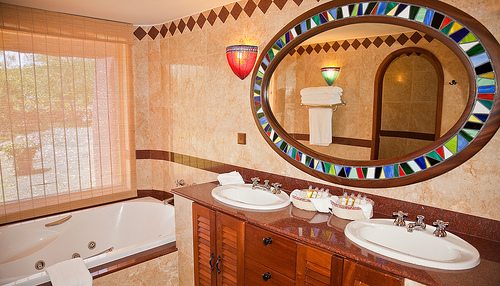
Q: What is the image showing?
A: It is showing a bathroom.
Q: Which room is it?
A: It is a bathroom.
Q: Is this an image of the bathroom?
A: Yes, it is showing the bathroom.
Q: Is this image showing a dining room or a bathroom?
A: It is showing a bathroom.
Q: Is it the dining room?
A: No, it is the bathroom.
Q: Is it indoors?
A: Yes, it is indoors.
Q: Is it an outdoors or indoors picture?
A: It is indoors.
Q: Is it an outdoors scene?
A: No, it is indoors.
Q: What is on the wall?
A: The sconce is on the wall.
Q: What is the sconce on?
A: The sconce is on the wall.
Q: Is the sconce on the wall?
A: Yes, the sconce is on the wall.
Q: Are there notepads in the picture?
A: No, there are no notepads.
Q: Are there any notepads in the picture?
A: No, there are no notepads.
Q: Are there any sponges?
A: No, there are no sponges.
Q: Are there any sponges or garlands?
A: No, there are no sponges or garlands.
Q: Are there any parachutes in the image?
A: No, there are no parachutes.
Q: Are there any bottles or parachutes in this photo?
A: No, there are no parachutes or bottles.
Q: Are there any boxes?
A: No, there are no boxes.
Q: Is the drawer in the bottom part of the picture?
A: Yes, the drawer is in the bottom of the image.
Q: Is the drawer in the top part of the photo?
A: No, the drawer is in the bottom of the image.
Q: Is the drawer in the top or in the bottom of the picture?
A: The drawer is in the bottom of the image.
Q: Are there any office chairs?
A: No, there are no office chairs.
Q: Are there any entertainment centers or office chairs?
A: No, there are no office chairs or entertainment centers.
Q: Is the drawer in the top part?
A: No, the drawer is in the bottom of the image.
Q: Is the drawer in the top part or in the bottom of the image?
A: The drawer is in the bottom of the image.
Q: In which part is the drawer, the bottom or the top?
A: The drawer is in the bottom of the image.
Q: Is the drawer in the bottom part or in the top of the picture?
A: The drawer is in the bottom of the image.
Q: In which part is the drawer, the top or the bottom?
A: The drawer is in the bottom of the image.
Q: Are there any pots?
A: No, there are no pots.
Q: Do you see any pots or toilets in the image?
A: No, there are no pots or toilets.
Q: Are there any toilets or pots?
A: No, there are no pots or toilets.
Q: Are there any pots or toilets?
A: No, there are no pots or toilets.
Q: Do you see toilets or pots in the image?
A: No, there are no pots or toilets.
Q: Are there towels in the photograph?
A: Yes, there is a towel.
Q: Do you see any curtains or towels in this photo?
A: Yes, there is a towel.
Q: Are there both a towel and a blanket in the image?
A: No, there is a towel but no blankets.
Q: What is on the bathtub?
A: The towel is on the bathtub.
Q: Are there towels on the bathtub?
A: Yes, there is a towel on the bathtub.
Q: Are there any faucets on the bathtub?
A: No, there is a towel on the bathtub.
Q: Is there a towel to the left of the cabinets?
A: Yes, there is a towel to the left of the cabinets.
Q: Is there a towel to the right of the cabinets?
A: No, the towel is to the left of the cabinets.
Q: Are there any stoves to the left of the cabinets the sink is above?
A: No, there is a towel to the left of the cabinets.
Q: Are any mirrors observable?
A: Yes, there is a mirror.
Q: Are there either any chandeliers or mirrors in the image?
A: Yes, there is a mirror.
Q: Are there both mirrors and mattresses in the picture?
A: No, there is a mirror but no mattresses.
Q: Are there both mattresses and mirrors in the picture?
A: No, there is a mirror but no mattresses.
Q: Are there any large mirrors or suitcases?
A: Yes, there is a large mirror.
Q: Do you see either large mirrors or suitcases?
A: Yes, there is a large mirror.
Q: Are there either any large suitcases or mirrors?
A: Yes, there is a large mirror.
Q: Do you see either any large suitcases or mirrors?
A: Yes, there is a large mirror.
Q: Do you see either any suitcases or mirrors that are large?
A: Yes, the mirror is large.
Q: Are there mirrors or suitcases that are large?
A: Yes, the mirror is large.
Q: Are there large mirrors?
A: Yes, there is a large mirror.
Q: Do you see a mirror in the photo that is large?
A: Yes, there is a mirror that is large.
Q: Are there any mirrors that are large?
A: Yes, there is a mirror that is large.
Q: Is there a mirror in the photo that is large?
A: Yes, there is a mirror that is large.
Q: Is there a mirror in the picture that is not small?
A: Yes, there is a large mirror.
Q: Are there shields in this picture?
A: No, there are no shields.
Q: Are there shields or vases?
A: No, there are no shields or vases.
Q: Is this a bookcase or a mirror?
A: This is a mirror.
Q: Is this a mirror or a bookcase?
A: This is a mirror.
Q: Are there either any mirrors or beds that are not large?
A: No, there is a mirror but it is large.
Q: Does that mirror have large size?
A: Yes, the mirror is large.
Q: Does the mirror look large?
A: Yes, the mirror is large.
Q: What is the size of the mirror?
A: The mirror is large.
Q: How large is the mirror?
A: The mirror is large.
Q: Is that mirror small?
A: No, the mirror is large.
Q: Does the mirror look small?
A: No, the mirror is large.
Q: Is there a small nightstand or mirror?
A: No, there is a mirror but it is large.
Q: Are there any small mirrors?
A: No, there is a mirror but it is large.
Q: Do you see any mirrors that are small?
A: No, there is a mirror but it is large.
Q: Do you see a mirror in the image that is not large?
A: No, there is a mirror but it is large.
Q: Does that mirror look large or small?
A: The mirror is large.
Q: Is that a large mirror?
A: Yes, that is a large mirror.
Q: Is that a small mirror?
A: No, that is a large mirror.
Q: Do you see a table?
A: Yes, there is a table.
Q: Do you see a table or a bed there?
A: Yes, there is a table.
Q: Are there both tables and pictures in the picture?
A: Yes, there are both a table and a picture.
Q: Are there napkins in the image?
A: No, there are no napkins.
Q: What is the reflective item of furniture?
A: The piece of furniture is a table.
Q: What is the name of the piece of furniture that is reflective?
A: The piece of furniture is a table.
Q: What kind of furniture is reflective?
A: The furniture is a table.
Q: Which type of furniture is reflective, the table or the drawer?
A: The table is reflective.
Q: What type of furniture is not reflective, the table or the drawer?
A: The drawer is not reflective.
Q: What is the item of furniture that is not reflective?
A: The piece of furniture is a drawer.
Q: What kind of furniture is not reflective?
A: The furniture is a drawer.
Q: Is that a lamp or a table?
A: That is a table.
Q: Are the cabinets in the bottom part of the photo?
A: Yes, the cabinets are in the bottom of the image.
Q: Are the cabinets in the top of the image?
A: No, the cabinets are in the bottom of the image.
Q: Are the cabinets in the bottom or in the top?
A: The cabinets are in the bottom of the image.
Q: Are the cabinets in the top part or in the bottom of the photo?
A: The cabinets are in the bottom of the image.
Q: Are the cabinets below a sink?
A: Yes, the cabinets are below a sink.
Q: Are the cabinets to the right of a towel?
A: Yes, the cabinets are to the right of a towel.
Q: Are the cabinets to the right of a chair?
A: No, the cabinets are to the right of a towel.